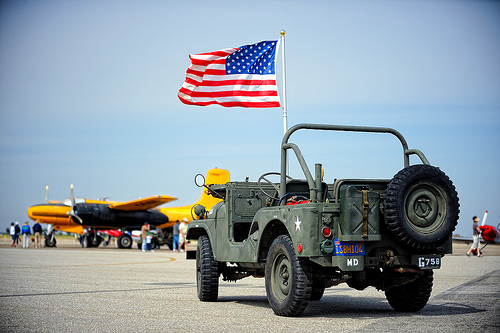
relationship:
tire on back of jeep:
[382, 163, 460, 252] [193, 113, 467, 316]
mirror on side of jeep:
[185, 174, 235, 206] [171, 109, 482, 324]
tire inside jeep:
[382, 163, 460, 252] [169, 157, 483, 329]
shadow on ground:
[241, 279, 491, 330] [21, 251, 473, 321]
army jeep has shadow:
[184, 122, 461, 316] [241, 279, 491, 330]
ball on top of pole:
[280, 25, 288, 40] [279, 30, 288, 150]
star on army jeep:
[289, 216, 306, 233] [195, 125, 461, 319]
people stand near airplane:
[9, 216, 69, 261] [19, 177, 248, 266]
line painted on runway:
[40, 241, 187, 274] [7, 237, 498, 330]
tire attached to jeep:
[382, 163, 460, 252] [193, 113, 467, 316]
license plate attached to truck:
[334, 242, 364, 258] [131, 115, 468, 330]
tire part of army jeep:
[267, 231, 309, 316] [184, 122, 461, 316]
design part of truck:
[287, 206, 310, 241] [187, 103, 468, 318]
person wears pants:
[467, 215, 484, 258] [470, 234, 480, 249]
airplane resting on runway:
[16, 177, 171, 260] [31, 249, 198, 332]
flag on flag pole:
[177, 28, 290, 179] [269, 30, 291, 150]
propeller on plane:
[64, 190, 82, 228] [19, 170, 244, 250]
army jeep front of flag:
[184, 122, 461, 316] [176, 39, 281, 121]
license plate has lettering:
[333, 238, 366, 256] [338, 241, 366, 253]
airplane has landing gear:
[27, 166, 231, 246] [80, 228, 135, 248]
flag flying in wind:
[175, 37, 282, 105] [16, 6, 484, 317]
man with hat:
[177, 219, 188, 255] [182, 217, 188, 222]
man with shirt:
[177, 219, 188, 255] [178, 222, 190, 235]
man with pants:
[177, 219, 188, 255] [175, 233, 186, 246]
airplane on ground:
[27, 166, 231, 246] [14, 220, 484, 327]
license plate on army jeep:
[333, 238, 366, 256] [184, 122, 461, 316]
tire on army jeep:
[380, 163, 465, 250] [184, 122, 461, 316]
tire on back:
[380, 163, 465, 250] [291, 119, 459, 303]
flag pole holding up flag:
[281, 36, 290, 180] [177, 37, 284, 110]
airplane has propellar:
[27, 166, 231, 246] [63, 185, 83, 223]